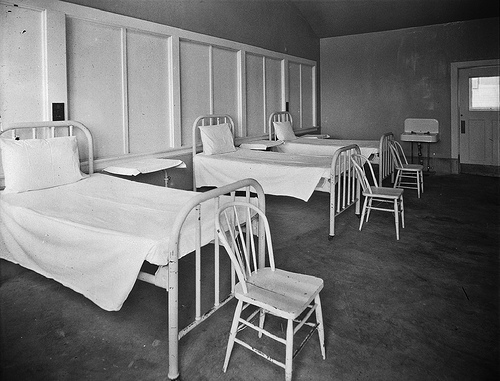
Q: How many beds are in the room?
A: Three.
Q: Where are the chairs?
A: Foot of the bed.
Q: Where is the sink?
A: Wall.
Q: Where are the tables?
A: Beside the beds.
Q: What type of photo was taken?
A: Black and white.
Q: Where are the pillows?
A: Beds.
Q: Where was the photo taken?
A: In an orphanage.